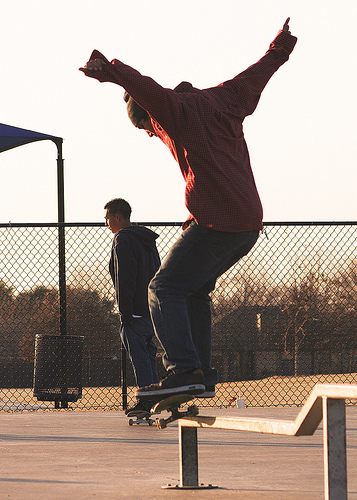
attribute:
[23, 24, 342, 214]
sky — radiant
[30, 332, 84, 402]
bin — black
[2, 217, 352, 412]
fence — chain linked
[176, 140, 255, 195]
jacket — red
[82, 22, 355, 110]
arms — outstrechted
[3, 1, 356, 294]
sky — cloudless, pleasant, summery, clear